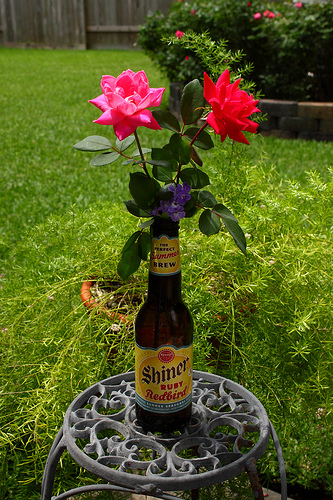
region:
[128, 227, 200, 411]
beer bottle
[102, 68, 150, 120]
pink flower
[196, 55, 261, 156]
red flower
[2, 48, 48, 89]
short green and brown grass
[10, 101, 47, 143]
short green and brown grass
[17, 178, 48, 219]
short green and brown grass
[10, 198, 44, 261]
short green and brown grass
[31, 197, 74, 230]
short green and brown grass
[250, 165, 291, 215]
short green and brown grass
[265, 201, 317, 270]
short green and brown grass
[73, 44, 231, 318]
flowers in a bottle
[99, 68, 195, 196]
the flower is pink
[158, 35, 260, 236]
the flower is pink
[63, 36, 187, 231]
the flower is pink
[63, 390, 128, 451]
the stool is gray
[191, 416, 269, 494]
the stool is gray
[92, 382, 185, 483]
the stool is gray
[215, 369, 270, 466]
the stool is gray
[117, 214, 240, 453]
bottle on the stool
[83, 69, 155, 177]
red flower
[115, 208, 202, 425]
brown beer bottle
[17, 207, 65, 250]
short green and brown grass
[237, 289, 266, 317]
short green and brown grass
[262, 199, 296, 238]
short green and brown grass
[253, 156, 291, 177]
short green and brown grass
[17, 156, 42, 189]
short green and brown grass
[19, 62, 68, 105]
short green and brown grass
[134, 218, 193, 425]
shiner ruby redbird beer bottle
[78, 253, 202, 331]
clay planter pot with soil and large fern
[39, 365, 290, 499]
metal garden stand meant for plants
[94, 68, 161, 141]
pink rose in full bloom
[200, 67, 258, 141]
red rose in full bloom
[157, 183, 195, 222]
tiny purple flowers tucked in bottle mouth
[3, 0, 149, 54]
wooden backyard fence around lawn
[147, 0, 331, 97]
large healthy rosebush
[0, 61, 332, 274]
very well kept green grass lawn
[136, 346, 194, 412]
yellow blue and red beer bottle lable